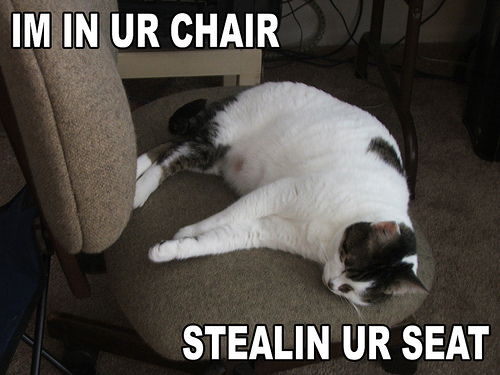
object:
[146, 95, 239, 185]
spots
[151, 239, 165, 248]
paw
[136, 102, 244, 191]
back legs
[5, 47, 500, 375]
carpet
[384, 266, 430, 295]
black ears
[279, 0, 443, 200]
wires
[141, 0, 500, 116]
table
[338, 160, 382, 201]
ground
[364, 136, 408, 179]
spot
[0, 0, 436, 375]
chair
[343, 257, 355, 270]
eyes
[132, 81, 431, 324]
bear cub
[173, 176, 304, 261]
front legs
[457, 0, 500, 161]
desktop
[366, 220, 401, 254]
pointy ears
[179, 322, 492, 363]
phrase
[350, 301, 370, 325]
whiskers